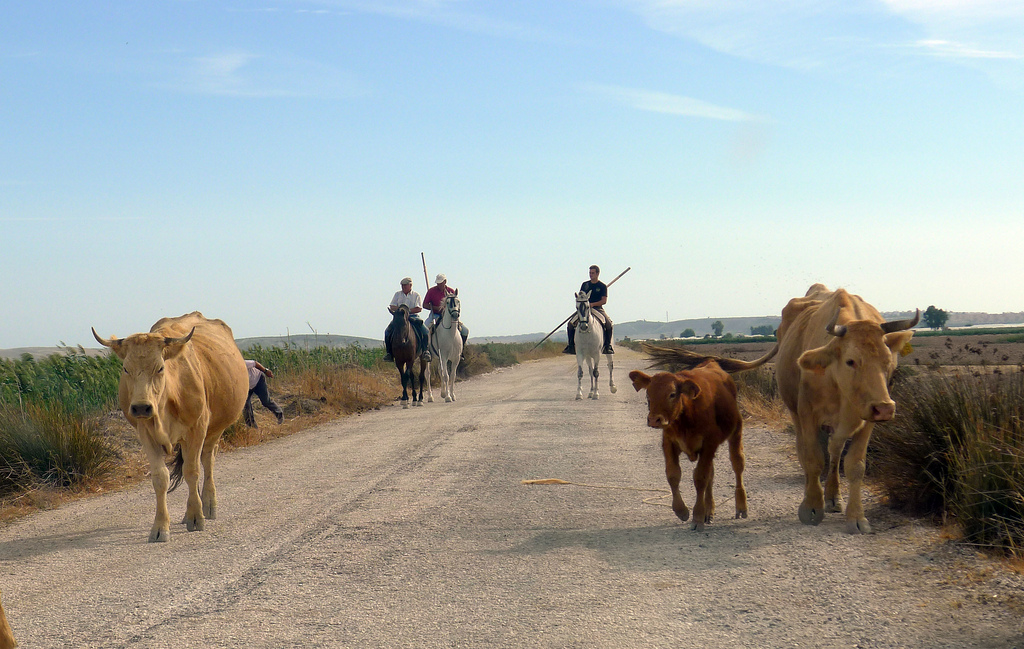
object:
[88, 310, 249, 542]
cow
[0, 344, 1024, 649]
road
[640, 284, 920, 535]
cow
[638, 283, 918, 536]
road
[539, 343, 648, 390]
road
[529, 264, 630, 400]
man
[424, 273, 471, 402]
man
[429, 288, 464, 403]
horse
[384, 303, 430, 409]
horse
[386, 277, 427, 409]
man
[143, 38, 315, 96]
clouds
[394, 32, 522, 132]
clouds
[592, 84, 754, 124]
clouds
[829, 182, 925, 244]
clouds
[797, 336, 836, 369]
ear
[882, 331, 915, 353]
ear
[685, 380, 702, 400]
ear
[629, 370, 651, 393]
ear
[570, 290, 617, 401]
horse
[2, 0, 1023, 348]
sky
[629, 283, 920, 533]
cow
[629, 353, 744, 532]
cow